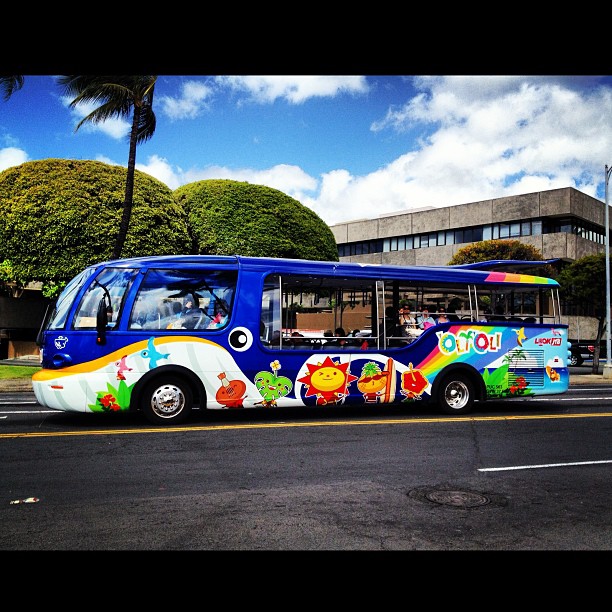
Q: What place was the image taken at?
A: It was taken at the road.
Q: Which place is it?
A: It is a road.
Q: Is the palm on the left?
A: Yes, the palm is on the left of the image.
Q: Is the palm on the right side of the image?
A: No, the palm is on the left of the image.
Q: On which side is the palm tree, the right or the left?
A: The palm tree is on the left of the image.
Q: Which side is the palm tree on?
A: The palm tree is on the left of the image.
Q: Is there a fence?
A: No, there are no fences.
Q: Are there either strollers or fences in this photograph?
A: No, there are no fences or strollers.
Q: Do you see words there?
A: Yes, there are words.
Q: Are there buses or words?
A: Yes, there are words.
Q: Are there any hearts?
A: Yes, there is a heart.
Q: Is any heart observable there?
A: Yes, there is a heart.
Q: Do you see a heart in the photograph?
A: Yes, there is a heart.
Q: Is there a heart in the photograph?
A: Yes, there is a heart.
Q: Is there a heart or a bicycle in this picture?
A: Yes, there is a heart.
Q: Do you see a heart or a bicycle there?
A: Yes, there is a heart.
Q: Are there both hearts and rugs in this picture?
A: No, there is a heart but no rugs.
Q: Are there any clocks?
A: No, there are no clocks.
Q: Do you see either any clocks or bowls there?
A: No, there are no clocks or bowls.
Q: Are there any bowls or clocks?
A: No, there are no clocks or bowls.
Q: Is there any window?
A: Yes, there are windows.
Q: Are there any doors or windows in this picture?
A: Yes, there are windows.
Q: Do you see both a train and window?
A: No, there are windows but no trains.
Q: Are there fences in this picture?
A: No, there are no fences.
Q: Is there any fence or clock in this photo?
A: No, there are no fences or clocks.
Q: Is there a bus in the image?
A: Yes, there is a bus.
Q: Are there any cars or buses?
A: Yes, there is a bus.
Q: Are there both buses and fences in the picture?
A: No, there is a bus but no fences.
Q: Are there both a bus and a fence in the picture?
A: No, there is a bus but no fences.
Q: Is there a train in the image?
A: No, there are no trains.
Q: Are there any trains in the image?
A: No, there are no trains.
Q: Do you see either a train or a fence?
A: No, there are no trains or fences.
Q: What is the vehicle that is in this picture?
A: The vehicle is a bus.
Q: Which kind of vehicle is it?
A: The vehicle is a bus.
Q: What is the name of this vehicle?
A: That is a bus.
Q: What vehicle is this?
A: That is a bus.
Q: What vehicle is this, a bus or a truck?
A: That is a bus.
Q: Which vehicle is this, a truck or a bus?
A: That is a bus.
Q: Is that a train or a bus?
A: That is a bus.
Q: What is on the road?
A: The bus is on the road.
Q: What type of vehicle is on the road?
A: The vehicle is a bus.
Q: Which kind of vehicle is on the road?
A: The vehicle is a bus.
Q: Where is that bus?
A: The bus is on the road.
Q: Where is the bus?
A: The bus is on the road.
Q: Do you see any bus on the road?
A: Yes, there is a bus on the road.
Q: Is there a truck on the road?
A: No, there is a bus on the road.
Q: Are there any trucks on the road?
A: No, there is a bus on the road.